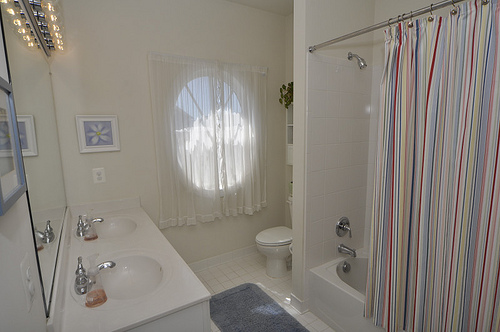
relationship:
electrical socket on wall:
[94, 168, 106, 184] [55, 4, 292, 250]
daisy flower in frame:
[87, 124, 111, 144] [75, 115, 119, 153]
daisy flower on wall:
[87, 124, 111, 144] [55, 4, 292, 250]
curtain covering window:
[152, 56, 267, 219] [176, 80, 257, 195]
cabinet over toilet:
[283, 92, 295, 165] [255, 195, 294, 276]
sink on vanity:
[102, 255, 162, 295] [67, 205, 211, 330]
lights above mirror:
[30, 1, 67, 53] [0, 5, 68, 322]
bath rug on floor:
[209, 284, 307, 331] [188, 247, 338, 332]